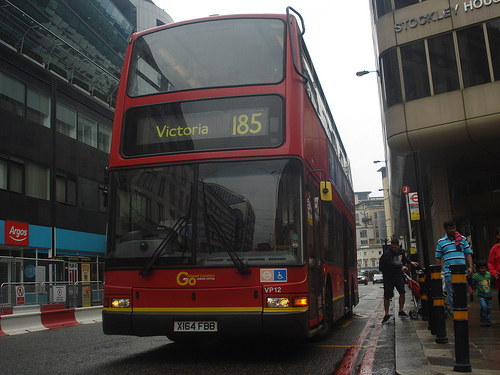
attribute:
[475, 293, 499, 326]
jeans — small, green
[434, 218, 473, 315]
man — dark color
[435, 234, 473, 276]
shirt — t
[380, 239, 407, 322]
man — looking down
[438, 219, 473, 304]
man — looking down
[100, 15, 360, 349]
bus — red, double decker, tall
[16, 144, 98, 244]
wall — blue